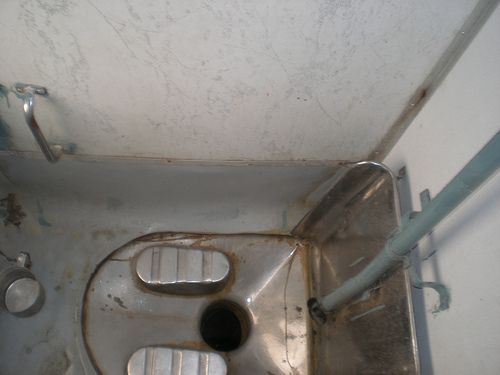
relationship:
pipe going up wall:
[308, 137, 498, 307] [399, 0, 499, 153]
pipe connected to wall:
[327, 185, 497, 282] [433, 220, 496, 373]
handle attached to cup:
[13, 250, 34, 270] [6, 250, 80, 325]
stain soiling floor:
[191, 233, 218, 244] [12, 207, 317, 374]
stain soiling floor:
[296, 245, 308, 287] [12, 207, 317, 374]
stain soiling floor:
[168, 340, 210, 349] [12, 207, 317, 374]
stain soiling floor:
[59, 268, 75, 281] [12, 207, 317, 374]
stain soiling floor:
[219, 286, 229, 293] [12, 207, 317, 374]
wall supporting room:
[69, 4, 409, 154] [4, 1, 499, 373]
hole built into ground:
[197, 297, 252, 352] [0, 209, 325, 372]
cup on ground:
[4, 240, 45, 320] [2, 230, 103, 374]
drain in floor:
[199, 297, 255, 352] [12, 207, 317, 374]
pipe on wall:
[322, 150, 499, 307] [380, 3, 497, 373]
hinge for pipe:
[392, 190, 451, 312] [308, 137, 498, 307]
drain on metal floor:
[193, 293, 253, 356] [0, 200, 319, 373]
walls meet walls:
[384, 0, 498, 372] [0, 0, 478, 162]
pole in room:
[318, 125, 498, 314] [4, 1, 499, 373]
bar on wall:
[8, 80, 78, 165] [2, 4, 477, 167]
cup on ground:
[5, 266, 55, 327] [2, 156, 380, 372]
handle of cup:
[16, 252, 31, 269] [1, 251, 43, 316]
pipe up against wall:
[320, 147, 485, 322] [380, 3, 497, 373]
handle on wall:
[12, 75, 84, 192] [4, 0, 452, 109]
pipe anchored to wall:
[320, 127, 499, 314] [380, 3, 497, 373]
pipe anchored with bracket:
[320, 127, 499, 314] [382, 186, 449, 313]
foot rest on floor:
[131, 232, 236, 296] [8, 165, 326, 374]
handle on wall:
[8, 80, 73, 165] [7, 45, 135, 192]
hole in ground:
[199, 298, 250, 353] [30, 157, 316, 372]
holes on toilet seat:
[188, 289, 266, 364] [82, 214, 370, 373]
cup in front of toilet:
[6, 245, 66, 311] [75, 185, 390, 359]